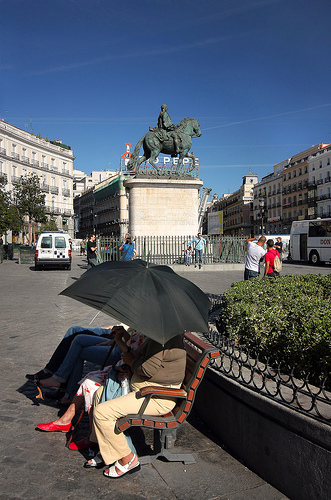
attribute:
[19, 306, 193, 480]
people — four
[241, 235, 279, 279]
people — standing, taking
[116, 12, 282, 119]
sky — blue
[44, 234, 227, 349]
umbrella — black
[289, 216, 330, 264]
bus — white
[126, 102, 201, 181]
statue — a man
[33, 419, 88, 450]
red shoes — bright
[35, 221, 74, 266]
van — white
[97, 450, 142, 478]
sandals — strapped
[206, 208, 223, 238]
sign — white, yellow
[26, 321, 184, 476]
people — Group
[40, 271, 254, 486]
bench — reddish brown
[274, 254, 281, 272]
backpack — tan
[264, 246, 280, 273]
shirt — red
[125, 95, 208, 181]
statue — man on horse, man, horse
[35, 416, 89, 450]
shoes — red